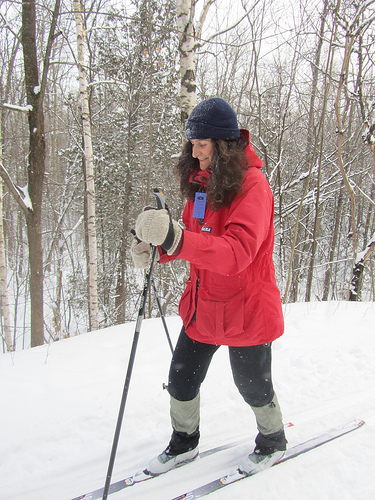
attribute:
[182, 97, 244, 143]
hat — black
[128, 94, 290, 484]
woman — skiing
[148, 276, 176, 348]
pole — right ski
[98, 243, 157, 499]
pole — left ski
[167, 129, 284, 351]
coat — red, heavy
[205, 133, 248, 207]
hair — brown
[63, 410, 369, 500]
skis — set, pair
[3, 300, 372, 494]
snow — lots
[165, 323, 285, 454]
pants — black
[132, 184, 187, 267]
gloves — grey, white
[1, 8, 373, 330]
trees — bare, dusted